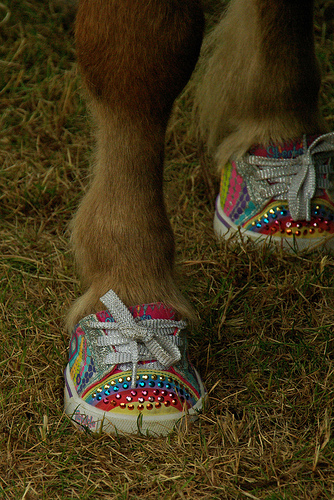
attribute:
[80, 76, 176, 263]
calf — proper-left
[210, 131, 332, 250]
shoe — second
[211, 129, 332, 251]
front foot — ungulate's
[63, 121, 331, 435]
shoes — multi-colored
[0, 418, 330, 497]
grass — trampled, barely watered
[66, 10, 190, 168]
calf — ungulate's, proper-left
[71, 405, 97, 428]
word — sparkle, red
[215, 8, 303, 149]
leg — longer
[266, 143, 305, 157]
word — Sketchers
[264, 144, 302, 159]
text — blue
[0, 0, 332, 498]
grass — short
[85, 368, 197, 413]
gemstones — fake, assorted colors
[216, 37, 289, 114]
fur — slightly thicker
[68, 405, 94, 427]
text — blue